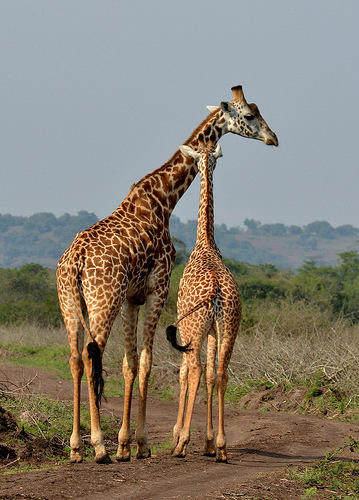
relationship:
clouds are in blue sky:
[177, 202, 197, 216] [0, 0, 359, 231]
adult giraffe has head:
[55, 83, 280, 465] [207, 79, 294, 152]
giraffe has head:
[165, 144, 243, 463] [176, 140, 227, 174]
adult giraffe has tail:
[55, 83, 280, 465] [63, 248, 106, 404]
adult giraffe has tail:
[55, 83, 280, 465] [64, 264, 108, 406]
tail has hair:
[165, 293, 216, 351] [165, 325, 194, 351]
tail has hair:
[68, 256, 106, 406] [87, 340, 109, 410]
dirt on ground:
[6, 374, 347, 498] [2, 327, 357, 497]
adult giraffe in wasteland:
[55, 83, 280, 465] [4, 259, 355, 498]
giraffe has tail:
[170, 145, 236, 461] [165, 293, 216, 351]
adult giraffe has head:
[55, 83, 280, 465] [202, 81, 279, 148]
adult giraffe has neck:
[55, 83, 280, 465] [146, 126, 197, 184]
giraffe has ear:
[165, 144, 243, 463] [180, 141, 198, 160]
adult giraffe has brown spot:
[54, 71, 281, 463] [135, 206, 154, 221]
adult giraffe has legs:
[55, 83, 280, 465] [58, 308, 157, 465]